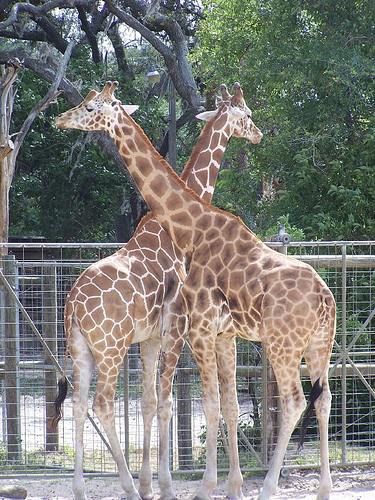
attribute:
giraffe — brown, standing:
[52, 81, 338, 499]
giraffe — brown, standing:
[58, 83, 263, 499]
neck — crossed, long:
[108, 117, 207, 264]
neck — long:
[182, 128, 235, 204]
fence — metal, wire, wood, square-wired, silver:
[0, 232, 373, 479]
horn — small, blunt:
[102, 81, 112, 97]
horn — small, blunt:
[111, 81, 120, 95]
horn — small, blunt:
[222, 84, 230, 100]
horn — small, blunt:
[232, 83, 244, 100]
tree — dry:
[0, 2, 217, 242]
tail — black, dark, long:
[296, 303, 332, 453]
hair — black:
[297, 381, 324, 454]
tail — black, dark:
[51, 302, 72, 430]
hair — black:
[52, 379, 69, 427]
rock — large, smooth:
[0, 488, 27, 499]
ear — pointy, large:
[122, 105, 140, 117]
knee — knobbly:
[157, 396, 173, 421]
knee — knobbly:
[141, 396, 157, 420]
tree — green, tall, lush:
[182, 0, 374, 254]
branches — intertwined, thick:
[0, 1, 205, 121]